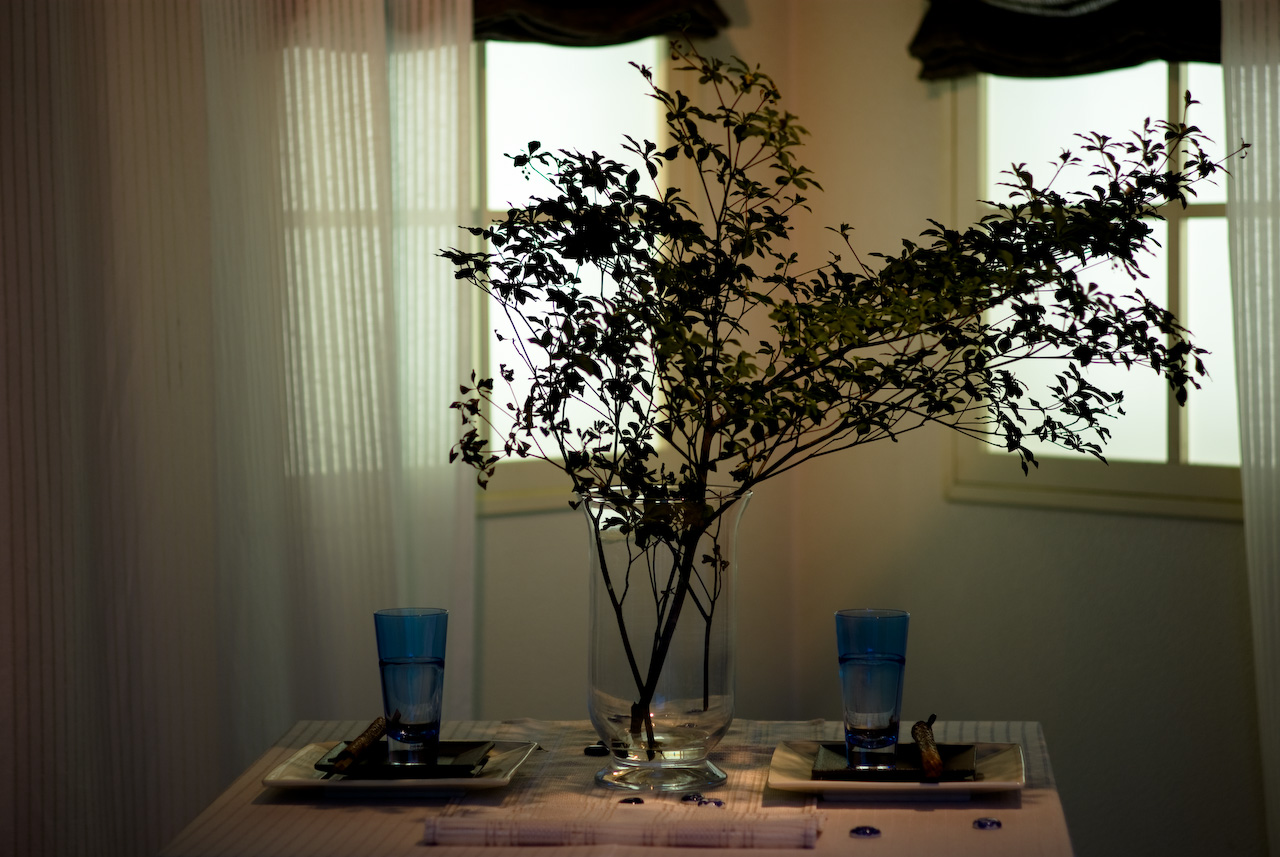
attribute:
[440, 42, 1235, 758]
branch — large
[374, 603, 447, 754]
cup — tall, blue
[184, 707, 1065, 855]
table — small, square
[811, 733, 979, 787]
plate — square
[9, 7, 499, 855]
curtain — sheer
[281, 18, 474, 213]
pane — glass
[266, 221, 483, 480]
pane — glass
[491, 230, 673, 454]
pane — glass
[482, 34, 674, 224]
pane — glass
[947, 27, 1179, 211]
pane — glass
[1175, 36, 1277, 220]
pane — glass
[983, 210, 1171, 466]
pane — glass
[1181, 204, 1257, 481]
pane — glass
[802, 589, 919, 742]
pane — glass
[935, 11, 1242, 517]
pane — glass